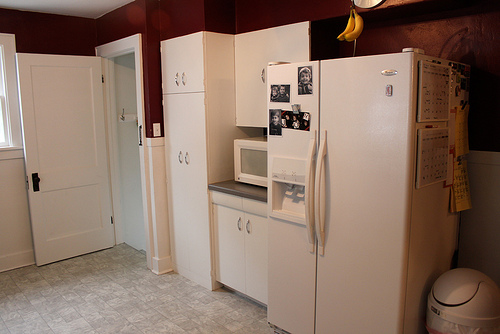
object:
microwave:
[233, 136, 267, 187]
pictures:
[298, 66, 314, 96]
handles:
[301, 122, 333, 256]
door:
[14, 52, 116, 267]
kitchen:
[0, 2, 499, 334]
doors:
[210, 189, 267, 305]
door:
[234, 27, 271, 128]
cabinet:
[231, 20, 310, 128]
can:
[424, 268, 498, 334]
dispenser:
[282, 184, 306, 217]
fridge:
[266, 46, 472, 334]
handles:
[304, 129, 328, 256]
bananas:
[337, 9, 356, 41]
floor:
[29, 267, 137, 319]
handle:
[32, 173, 41, 193]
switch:
[153, 123, 162, 137]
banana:
[342, 5, 363, 42]